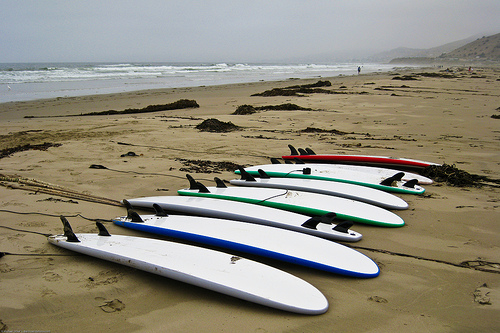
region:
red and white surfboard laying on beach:
[278, 141, 453, 172]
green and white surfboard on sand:
[235, 157, 435, 192]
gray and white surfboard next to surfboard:
[217, 172, 409, 208]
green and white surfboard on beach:
[175, 170, 406, 225]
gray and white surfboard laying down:
[120, 190, 356, 235]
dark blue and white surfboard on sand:
[112, 205, 377, 280]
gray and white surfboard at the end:
[42, 215, 328, 311]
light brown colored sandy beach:
[0, 67, 495, 327]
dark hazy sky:
[0, 0, 495, 55]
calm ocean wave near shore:
[0, 60, 411, 81]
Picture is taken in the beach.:
[27, 35, 490, 286]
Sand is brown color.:
[31, 125, 156, 195]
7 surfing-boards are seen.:
[57, 130, 442, 330]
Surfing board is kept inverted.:
[55, 93, 442, 316]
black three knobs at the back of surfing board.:
[52, 207, 112, 250]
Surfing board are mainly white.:
[77, 123, 422, 313]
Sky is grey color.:
[30, 20, 131, 53]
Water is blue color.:
[1, 55, 156, 88]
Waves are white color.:
[42, 65, 163, 73]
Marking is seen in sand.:
[1, 128, 188, 226]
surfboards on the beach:
[36, 200, 464, 302]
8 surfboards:
[2, 128, 492, 291]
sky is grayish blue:
[8, 4, 395, 89]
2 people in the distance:
[326, 42, 495, 108]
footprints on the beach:
[16, 141, 118, 327]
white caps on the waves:
[14, 39, 297, 111]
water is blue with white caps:
[11, 40, 211, 97]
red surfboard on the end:
[271, 150, 436, 192]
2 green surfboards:
[134, 129, 446, 284]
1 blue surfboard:
[96, 157, 395, 282]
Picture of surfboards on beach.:
[21, 31, 480, 316]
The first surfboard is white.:
[50, 226, 338, 317]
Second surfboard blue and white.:
[110, 200, 383, 265]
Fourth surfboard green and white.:
[187, 166, 407, 231]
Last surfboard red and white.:
[287, 136, 464, 176]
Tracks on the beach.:
[12, 156, 107, 209]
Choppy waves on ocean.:
[18, 56, 274, 96]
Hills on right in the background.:
[390, 35, 496, 70]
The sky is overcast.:
[37, 12, 252, 58]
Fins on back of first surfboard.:
[52, 212, 120, 242]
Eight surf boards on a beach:
[46, 151, 453, 316]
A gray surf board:
[51, 229, 326, 315]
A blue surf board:
[113, 211, 378, 276]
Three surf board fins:
[58, 215, 109, 244]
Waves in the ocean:
[0, 60, 410, 106]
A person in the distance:
[356, 64, 362, 75]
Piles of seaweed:
[21, 77, 358, 132]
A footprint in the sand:
[93, 291, 125, 316]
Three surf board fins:
[186, 172, 226, 192]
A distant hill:
[391, 31, 498, 67]